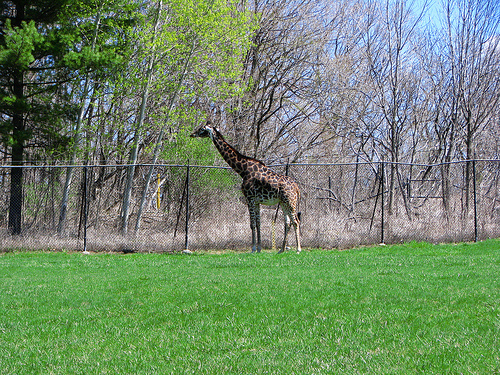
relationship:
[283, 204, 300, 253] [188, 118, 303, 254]
legs on giraffe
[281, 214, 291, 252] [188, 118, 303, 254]
legs on giraffe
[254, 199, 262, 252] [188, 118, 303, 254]
legs on giraffe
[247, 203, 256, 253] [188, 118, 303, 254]
legs on giraffe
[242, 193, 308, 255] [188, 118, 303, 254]
legs on giraffe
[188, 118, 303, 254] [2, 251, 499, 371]
giraffe standing in grass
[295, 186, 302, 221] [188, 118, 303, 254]
tail of giraffe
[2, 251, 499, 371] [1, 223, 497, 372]
grass on ground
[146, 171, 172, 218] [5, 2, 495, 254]
pipe in woods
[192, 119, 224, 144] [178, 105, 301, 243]
head of a giraffe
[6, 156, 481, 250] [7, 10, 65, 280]
fence going from left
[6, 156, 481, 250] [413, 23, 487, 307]
fence going to right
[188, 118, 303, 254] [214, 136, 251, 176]
giraffe with neck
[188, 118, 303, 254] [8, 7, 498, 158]
giraffe eating from trees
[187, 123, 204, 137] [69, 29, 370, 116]
face by trees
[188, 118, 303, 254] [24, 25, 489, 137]
giraffe by tree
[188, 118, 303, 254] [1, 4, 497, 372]
giraffe at zoo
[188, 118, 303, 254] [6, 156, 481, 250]
giraffe beside fence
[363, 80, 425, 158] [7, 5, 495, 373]
trees in photo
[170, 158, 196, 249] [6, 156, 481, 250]
poles holding fence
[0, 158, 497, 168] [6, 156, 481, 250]
pole running along fence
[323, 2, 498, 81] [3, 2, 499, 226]
sky behind trees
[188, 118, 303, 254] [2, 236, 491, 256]
giraffe standing on fence line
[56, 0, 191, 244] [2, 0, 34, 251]
small sapling by big tree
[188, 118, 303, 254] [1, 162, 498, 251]
giraffe standing next to fence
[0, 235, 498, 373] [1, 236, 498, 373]
field of grass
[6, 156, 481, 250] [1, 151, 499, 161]
fence has barbed wire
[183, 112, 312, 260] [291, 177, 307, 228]
giraffe at end of h tail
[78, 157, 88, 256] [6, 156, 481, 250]
fencepost holding up fence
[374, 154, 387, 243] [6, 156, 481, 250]
fencepost holding up fence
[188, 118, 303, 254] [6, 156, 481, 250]
giraffe by fence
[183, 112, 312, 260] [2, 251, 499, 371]
giraffe standing on grass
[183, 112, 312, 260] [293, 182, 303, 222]
giraffe has tail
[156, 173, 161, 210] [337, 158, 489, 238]
pipe behind fence